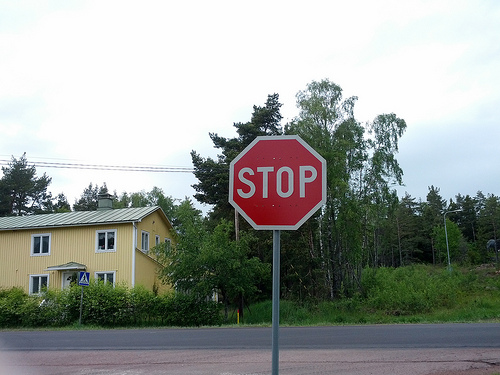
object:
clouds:
[97, 45, 237, 132]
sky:
[2, 1, 497, 208]